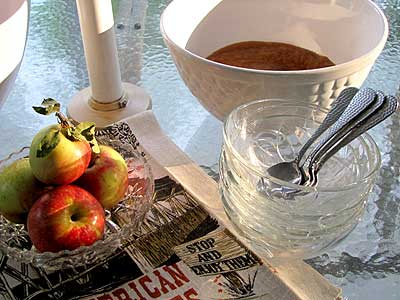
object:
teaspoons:
[264, 86, 358, 186]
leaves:
[31, 97, 64, 115]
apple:
[29, 111, 93, 187]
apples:
[75, 145, 129, 210]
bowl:
[0, 239, 121, 270]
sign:
[216, 268, 262, 299]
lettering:
[185, 236, 255, 276]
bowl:
[159, 0, 389, 124]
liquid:
[207, 40, 336, 70]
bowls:
[218, 97, 381, 261]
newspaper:
[3, 266, 187, 299]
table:
[0, 0, 399, 299]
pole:
[75, 0, 127, 111]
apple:
[28, 183, 106, 252]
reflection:
[117, 0, 146, 86]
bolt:
[119, 99, 127, 107]